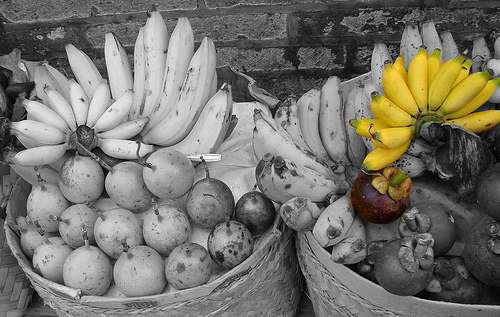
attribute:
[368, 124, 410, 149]
banana — yellow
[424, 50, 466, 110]
banana — yellow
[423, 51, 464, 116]
banana — yellow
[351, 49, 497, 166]
banana — yellow, ripe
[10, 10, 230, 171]
banana — yellow, ripe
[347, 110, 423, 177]
banana — yellow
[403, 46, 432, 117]
banana — yellow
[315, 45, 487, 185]
banana — yellow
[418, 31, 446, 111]
banana — yellow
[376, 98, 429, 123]
banana — yellow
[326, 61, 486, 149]
banana — yellow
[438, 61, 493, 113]
banana — yellow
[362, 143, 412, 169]
banana — yellow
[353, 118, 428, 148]
bananas — yellow, ripe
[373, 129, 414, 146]
banana — ripe, yellow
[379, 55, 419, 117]
banana — yellow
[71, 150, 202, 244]
fruits — round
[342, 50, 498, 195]
banana — yellow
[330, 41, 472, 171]
banana — yellow